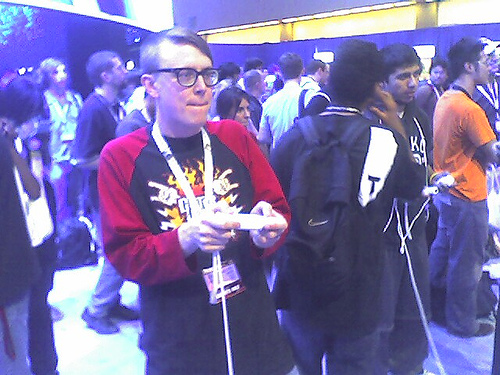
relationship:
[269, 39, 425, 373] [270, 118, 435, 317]
man wearing backpack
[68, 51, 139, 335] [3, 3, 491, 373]
man standing in room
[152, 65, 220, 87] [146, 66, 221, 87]
frame on glasses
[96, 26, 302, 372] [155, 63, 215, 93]
man wearing glasses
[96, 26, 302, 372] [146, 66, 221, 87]
man wearing glasses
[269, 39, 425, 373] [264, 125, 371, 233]
man wearing a backpack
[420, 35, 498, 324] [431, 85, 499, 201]
man wearing a t-shirt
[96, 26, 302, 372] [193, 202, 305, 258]
man playing a video game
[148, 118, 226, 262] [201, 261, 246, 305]
lanyard with name badge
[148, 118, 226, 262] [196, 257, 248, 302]
lanyard with name tag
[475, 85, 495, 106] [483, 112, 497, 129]
landyard with name tag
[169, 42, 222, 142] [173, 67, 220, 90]
face wearing glasses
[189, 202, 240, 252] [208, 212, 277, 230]
hand holding controller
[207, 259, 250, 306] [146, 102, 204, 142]
tag hanging on neck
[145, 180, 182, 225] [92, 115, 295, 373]
logo painted on shirt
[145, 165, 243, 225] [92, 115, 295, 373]
logo painted on shirt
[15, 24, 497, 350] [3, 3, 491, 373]
crowd standing in a room